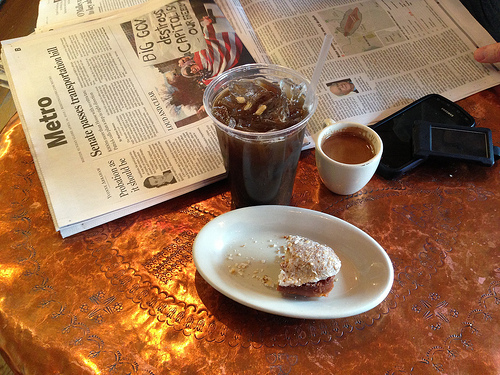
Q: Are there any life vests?
A: No, there are no life vests.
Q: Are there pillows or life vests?
A: No, there are no life vests or pillows.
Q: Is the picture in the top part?
A: Yes, the picture is in the top of the image.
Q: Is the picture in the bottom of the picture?
A: No, the picture is in the top of the image.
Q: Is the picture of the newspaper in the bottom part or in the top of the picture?
A: The picture is in the top of the image.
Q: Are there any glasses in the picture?
A: No, there are no glasses.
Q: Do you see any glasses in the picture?
A: No, there are no glasses.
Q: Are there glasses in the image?
A: No, there are no glasses.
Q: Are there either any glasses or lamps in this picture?
A: No, there are no glasses or lamps.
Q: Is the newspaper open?
A: Yes, the newspaper is open.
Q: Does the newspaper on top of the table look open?
A: Yes, the newspaper is open.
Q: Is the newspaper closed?
A: No, the newspaper is open.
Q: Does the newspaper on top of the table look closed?
A: No, the newspaper is open.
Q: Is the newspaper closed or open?
A: The newspaper is open.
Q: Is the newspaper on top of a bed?
A: No, the newspaper is on top of the table.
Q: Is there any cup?
A: Yes, there is a cup.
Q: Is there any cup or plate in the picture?
A: Yes, there is a cup.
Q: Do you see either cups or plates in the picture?
A: Yes, there is a cup.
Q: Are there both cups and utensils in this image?
A: No, there is a cup but no utensils.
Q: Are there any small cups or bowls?
A: Yes, there is a small cup.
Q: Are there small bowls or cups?
A: Yes, there is a small cup.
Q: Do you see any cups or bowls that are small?
A: Yes, the cup is small.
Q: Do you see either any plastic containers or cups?
A: Yes, there is a plastic cup.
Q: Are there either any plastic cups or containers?
A: Yes, there is a plastic cup.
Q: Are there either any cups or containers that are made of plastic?
A: Yes, the cup is made of plastic.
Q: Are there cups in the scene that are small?
A: Yes, there is a small cup.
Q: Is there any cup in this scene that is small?
A: Yes, there is a cup that is small.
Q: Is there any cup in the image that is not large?
A: Yes, there is a small cup.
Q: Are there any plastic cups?
A: Yes, there is a cup that is made of plastic.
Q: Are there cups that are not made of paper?
A: Yes, there is a cup that is made of plastic.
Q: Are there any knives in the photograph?
A: No, there are no knives.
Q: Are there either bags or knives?
A: No, there are no knives or bags.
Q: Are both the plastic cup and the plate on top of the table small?
A: Yes, both the cup and the plate are small.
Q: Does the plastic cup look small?
A: Yes, the cup is small.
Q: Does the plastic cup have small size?
A: Yes, the cup is small.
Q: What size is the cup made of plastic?
A: The cup is small.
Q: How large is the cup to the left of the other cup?
A: The cup is small.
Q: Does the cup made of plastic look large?
A: No, the cup is small.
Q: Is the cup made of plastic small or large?
A: The cup is small.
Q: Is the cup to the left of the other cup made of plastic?
A: Yes, the cup is made of plastic.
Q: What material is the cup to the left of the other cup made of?
A: The cup is made of plastic.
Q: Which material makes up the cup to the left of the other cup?
A: The cup is made of plastic.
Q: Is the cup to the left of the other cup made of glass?
A: No, the cup is made of plastic.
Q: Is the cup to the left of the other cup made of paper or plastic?
A: The cup is made of plastic.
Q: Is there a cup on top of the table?
A: Yes, there is a cup on top of the table.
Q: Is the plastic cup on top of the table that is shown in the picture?
A: Yes, the cup is on top of the table.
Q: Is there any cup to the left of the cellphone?
A: Yes, there is a cup to the left of the cellphone.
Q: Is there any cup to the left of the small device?
A: Yes, there is a cup to the left of the cellphone.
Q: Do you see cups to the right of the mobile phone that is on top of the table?
A: No, the cup is to the left of the cellphone.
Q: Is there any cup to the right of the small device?
A: No, the cup is to the left of the cellphone.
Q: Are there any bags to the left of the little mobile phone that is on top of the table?
A: No, there is a cup to the left of the mobile phone.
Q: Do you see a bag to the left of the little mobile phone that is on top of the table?
A: No, there is a cup to the left of the mobile phone.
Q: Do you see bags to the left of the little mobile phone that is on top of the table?
A: No, there is a cup to the left of the mobile phone.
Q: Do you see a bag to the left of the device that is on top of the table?
A: No, there is a cup to the left of the mobile phone.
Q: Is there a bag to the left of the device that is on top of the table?
A: No, there is a cup to the left of the mobile phone.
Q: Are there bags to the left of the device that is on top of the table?
A: No, there is a cup to the left of the mobile phone.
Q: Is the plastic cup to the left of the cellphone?
A: Yes, the cup is to the left of the cellphone.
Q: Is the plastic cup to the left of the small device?
A: Yes, the cup is to the left of the cellphone.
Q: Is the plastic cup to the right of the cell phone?
A: No, the cup is to the left of the cell phone.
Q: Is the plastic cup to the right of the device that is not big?
A: No, the cup is to the left of the cell phone.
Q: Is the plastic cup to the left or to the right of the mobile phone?
A: The cup is to the left of the mobile phone.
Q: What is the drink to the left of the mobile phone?
A: The drink is soda.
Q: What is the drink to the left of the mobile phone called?
A: The drink is soda.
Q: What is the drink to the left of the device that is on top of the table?
A: The drink is soda.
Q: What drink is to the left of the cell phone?
A: The drink is soda.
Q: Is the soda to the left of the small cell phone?
A: Yes, the soda is to the left of the cell phone.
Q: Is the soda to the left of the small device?
A: Yes, the soda is to the left of the cell phone.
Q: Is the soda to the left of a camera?
A: No, the soda is to the left of the cell phone.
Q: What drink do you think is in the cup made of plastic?
A: The drink is soda.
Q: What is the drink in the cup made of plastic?
A: The drink is soda.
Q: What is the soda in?
A: The soda is in the cup.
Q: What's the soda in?
A: The soda is in the cup.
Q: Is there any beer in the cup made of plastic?
A: No, there is soda in the cup.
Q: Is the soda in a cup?
A: Yes, the soda is in a cup.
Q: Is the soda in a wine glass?
A: No, the soda is in a cup.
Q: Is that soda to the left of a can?
A: No, the soda is to the left of the cup.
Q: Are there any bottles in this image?
A: No, there are no bottles.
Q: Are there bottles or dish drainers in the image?
A: No, there are no bottles or dish drainers.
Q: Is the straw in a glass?
A: No, the straw is in the cup.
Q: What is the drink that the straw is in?
A: The drink is soda.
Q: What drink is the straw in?
A: The straw is in the soda.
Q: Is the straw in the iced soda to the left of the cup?
A: Yes, the straw is in the soda.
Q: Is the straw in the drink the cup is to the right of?
A: Yes, the straw is in the soda.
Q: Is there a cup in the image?
A: Yes, there is a cup.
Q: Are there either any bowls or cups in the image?
A: Yes, there is a cup.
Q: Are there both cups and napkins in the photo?
A: No, there is a cup but no napkins.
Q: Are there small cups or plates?
A: Yes, there is a small cup.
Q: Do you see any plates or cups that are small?
A: Yes, the cup is small.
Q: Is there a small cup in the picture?
A: Yes, there is a small cup.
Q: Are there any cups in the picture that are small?
A: Yes, there is a cup that is small.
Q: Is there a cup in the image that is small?
A: Yes, there is a cup that is small.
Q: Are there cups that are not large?
A: Yes, there is a small cup.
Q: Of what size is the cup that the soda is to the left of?
A: The cup is small.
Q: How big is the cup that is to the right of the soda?
A: The cup is small.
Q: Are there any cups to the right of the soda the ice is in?
A: Yes, there is a cup to the right of the soda.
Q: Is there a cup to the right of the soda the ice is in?
A: Yes, there is a cup to the right of the soda.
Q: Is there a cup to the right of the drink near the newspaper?
A: Yes, there is a cup to the right of the soda.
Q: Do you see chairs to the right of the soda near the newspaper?
A: No, there is a cup to the right of the soda.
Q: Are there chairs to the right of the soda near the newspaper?
A: No, there is a cup to the right of the soda.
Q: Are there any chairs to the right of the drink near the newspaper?
A: No, there is a cup to the right of the soda.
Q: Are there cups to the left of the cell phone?
A: Yes, there is a cup to the left of the cell phone.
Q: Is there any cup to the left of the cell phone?
A: Yes, there is a cup to the left of the cell phone.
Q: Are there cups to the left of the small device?
A: Yes, there is a cup to the left of the cell phone.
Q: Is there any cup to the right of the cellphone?
A: No, the cup is to the left of the cellphone.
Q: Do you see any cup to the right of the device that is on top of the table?
A: No, the cup is to the left of the cellphone.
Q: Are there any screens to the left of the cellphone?
A: No, there is a cup to the left of the cellphone.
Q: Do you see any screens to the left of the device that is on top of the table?
A: No, there is a cup to the left of the cellphone.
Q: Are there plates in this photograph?
A: Yes, there is a plate.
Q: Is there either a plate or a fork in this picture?
A: Yes, there is a plate.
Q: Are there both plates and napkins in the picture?
A: No, there is a plate but no napkins.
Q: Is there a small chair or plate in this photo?
A: Yes, there is a small plate.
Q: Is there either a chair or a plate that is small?
A: Yes, the plate is small.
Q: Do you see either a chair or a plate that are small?
A: Yes, the plate is small.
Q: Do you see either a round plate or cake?
A: Yes, there is a round plate.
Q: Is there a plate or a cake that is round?
A: Yes, the plate is round.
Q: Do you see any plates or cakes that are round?
A: Yes, the plate is round.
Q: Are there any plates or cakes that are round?
A: Yes, the plate is round.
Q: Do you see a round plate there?
A: Yes, there is a round plate.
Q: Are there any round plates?
A: Yes, there is a round plate.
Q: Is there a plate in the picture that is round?
A: Yes, there is a plate that is round.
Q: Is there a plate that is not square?
A: Yes, there is a round plate.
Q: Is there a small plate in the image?
A: Yes, there is a small plate.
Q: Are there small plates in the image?
A: Yes, there is a small plate.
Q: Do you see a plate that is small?
A: Yes, there is a plate that is small.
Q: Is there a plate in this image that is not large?
A: Yes, there is a small plate.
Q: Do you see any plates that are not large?
A: Yes, there is a small plate.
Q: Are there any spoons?
A: No, there are no spoons.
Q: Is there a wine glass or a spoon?
A: No, there are no spoons or wine glasses.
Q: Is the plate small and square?
A: No, the plate is small but round.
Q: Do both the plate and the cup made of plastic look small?
A: Yes, both the plate and the cup are small.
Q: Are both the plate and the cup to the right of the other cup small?
A: Yes, both the plate and the cup are small.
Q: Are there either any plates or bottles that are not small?
A: No, there is a plate but it is small.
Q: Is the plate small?
A: Yes, the plate is small.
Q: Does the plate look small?
A: Yes, the plate is small.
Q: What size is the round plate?
A: The plate is small.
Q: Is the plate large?
A: No, the plate is small.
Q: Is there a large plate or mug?
A: No, there is a plate but it is small.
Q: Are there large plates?
A: No, there is a plate but it is small.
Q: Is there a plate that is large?
A: No, there is a plate but it is small.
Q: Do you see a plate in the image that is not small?
A: No, there is a plate but it is small.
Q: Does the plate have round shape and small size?
A: Yes, the plate is round and small.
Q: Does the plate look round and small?
A: Yes, the plate is round and small.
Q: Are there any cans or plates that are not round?
A: No, there is a plate but it is round.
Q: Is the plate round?
A: Yes, the plate is round.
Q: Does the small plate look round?
A: Yes, the plate is round.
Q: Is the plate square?
A: No, the plate is round.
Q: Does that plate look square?
A: No, the plate is round.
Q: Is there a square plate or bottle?
A: No, there is a plate but it is round.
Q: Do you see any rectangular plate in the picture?
A: No, there is a plate but it is round.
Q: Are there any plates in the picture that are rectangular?
A: No, there is a plate but it is round.